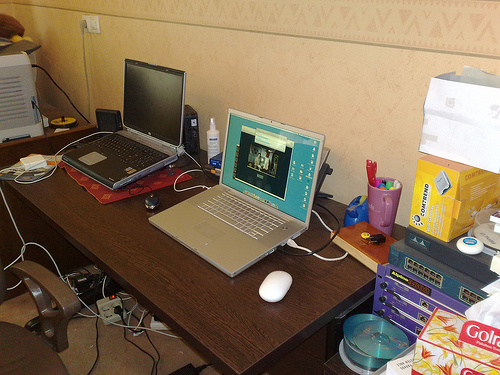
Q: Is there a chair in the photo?
A: Yes, there is a chair.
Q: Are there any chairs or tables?
A: Yes, there is a chair.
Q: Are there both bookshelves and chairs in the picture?
A: No, there is a chair but no bookshelves.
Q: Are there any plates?
A: No, there are no plates.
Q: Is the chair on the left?
A: Yes, the chair is on the left of the image.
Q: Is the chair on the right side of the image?
A: No, the chair is on the left of the image.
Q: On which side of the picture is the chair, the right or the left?
A: The chair is on the left of the image.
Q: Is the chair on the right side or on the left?
A: The chair is on the left of the image.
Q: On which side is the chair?
A: The chair is on the left of the image.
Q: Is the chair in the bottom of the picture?
A: Yes, the chair is in the bottom of the image.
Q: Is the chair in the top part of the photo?
A: No, the chair is in the bottom of the image.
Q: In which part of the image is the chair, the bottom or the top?
A: The chair is in the bottom of the image.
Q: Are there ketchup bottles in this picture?
A: No, there are no ketchup bottles.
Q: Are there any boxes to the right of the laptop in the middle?
A: Yes, there is a box to the right of the laptop.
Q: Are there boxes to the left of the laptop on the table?
A: No, the box is to the right of the laptop.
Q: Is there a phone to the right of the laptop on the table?
A: No, there is a box to the right of the laptop.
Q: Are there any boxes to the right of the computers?
A: Yes, there is a box to the right of the computers.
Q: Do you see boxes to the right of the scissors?
A: Yes, there is a box to the right of the scissors.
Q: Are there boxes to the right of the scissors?
A: Yes, there is a box to the right of the scissors.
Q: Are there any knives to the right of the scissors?
A: No, there is a box to the right of the scissors.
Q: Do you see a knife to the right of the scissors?
A: No, there is a box to the right of the scissors.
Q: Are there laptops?
A: Yes, there is a laptop.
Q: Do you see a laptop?
A: Yes, there is a laptop.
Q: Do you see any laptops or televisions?
A: Yes, there is a laptop.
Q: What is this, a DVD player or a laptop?
A: This is a laptop.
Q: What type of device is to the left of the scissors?
A: The device is a laptop.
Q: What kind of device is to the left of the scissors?
A: The device is a laptop.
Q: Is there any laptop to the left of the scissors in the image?
A: Yes, there is a laptop to the left of the scissors.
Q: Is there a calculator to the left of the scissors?
A: No, there is a laptop to the left of the scissors.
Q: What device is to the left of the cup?
A: The device is a laptop.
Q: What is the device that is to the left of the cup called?
A: The device is a laptop.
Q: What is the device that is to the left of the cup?
A: The device is a laptop.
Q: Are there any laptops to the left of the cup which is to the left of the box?
A: Yes, there is a laptop to the left of the cup.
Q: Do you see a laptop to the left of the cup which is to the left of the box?
A: Yes, there is a laptop to the left of the cup.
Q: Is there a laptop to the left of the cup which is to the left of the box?
A: Yes, there is a laptop to the left of the cup.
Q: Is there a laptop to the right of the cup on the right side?
A: No, the laptop is to the left of the cup.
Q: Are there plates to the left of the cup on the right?
A: No, there is a laptop to the left of the cup.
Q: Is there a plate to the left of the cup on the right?
A: No, there is a laptop to the left of the cup.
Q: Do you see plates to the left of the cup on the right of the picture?
A: No, there is a laptop to the left of the cup.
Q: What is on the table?
A: The laptop is on the table.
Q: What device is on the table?
A: The device is a laptop.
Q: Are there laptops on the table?
A: Yes, there is a laptop on the table.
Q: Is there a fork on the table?
A: No, there is a laptop on the table.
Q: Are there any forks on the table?
A: No, there is a laptop on the table.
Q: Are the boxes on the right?
A: Yes, the boxes are on the right of the image.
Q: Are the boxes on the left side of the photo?
A: No, the boxes are on the right of the image.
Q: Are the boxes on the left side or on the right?
A: The boxes are on the right of the image.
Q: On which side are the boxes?
A: The boxes are on the right of the image.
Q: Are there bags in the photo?
A: No, there are no bags.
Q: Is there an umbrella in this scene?
A: No, there are no umbrellas.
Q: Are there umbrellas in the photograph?
A: No, there are no umbrellas.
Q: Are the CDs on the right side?
A: Yes, the CDs are on the right of the image.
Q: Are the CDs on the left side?
A: No, the CDs are on the right of the image.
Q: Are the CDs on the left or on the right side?
A: The CDs are on the right of the image.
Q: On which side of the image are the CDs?
A: The CDs are on the right of the image.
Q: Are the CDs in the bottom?
A: Yes, the CDs are in the bottom of the image.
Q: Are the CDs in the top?
A: No, the CDs are in the bottom of the image.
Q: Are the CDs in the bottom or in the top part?
A: The CDs are in the bottom of the image.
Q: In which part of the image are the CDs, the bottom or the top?
A: The CDs are in the bottom of the image.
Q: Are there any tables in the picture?
A: Yes, there is a table.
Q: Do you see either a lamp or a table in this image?
A: Yes, there is a table.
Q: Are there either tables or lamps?
A: Yes, there is a table.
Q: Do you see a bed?
A: No, there are no beds.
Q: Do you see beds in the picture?
A: No, there are no beds.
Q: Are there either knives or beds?
A: No, there are no beds or knives.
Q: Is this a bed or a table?
A: This is a table.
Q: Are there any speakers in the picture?
A: No, there are no speakers.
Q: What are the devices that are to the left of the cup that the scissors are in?
A: The devices are computers.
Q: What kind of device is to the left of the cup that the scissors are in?
A: The devices are computers.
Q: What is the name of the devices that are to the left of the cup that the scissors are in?
A: The devices are computers.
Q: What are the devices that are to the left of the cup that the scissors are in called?
A: The devices are computers.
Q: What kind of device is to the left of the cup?
A: The devices are computers.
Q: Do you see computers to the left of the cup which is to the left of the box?
A: Yes, there are computers to the left of the cup.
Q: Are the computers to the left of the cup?
A: Yes, the computers are to the left of the cup.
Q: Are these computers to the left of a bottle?
A: No, the computers are to the left of the cup.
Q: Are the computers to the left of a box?
A: Yes, the computers are to the left of a box.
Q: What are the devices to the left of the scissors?
A: The devices are computers.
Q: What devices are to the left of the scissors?
A: The devices are computers.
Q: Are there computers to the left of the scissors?
A: Yes, there are computers to the left of the scissors.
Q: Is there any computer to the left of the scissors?
A: Yes, there are computers to the left of the scissors.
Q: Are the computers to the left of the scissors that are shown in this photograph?
A: Yes, the computers are to the left of the scissors.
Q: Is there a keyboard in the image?
A: Yes, there is a keyboard.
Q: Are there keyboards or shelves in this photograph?
A: Yes, there is a keyboard.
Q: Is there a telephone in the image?
A: No, there are no phones.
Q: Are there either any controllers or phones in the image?
A: No, there are no phones or controllers.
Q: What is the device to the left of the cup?
A: The device is a keyboard.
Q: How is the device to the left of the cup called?
A: The device is a keyboard.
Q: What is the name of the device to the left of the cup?
A: The device is a keyboard.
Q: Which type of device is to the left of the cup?
A: The device is a keyboard.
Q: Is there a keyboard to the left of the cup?
A: Yes, there is a keyboard to the left of the cup.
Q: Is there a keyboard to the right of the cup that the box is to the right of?
A: No, the keyboard is to the left of the cup.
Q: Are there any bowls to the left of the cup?
A: No, there is a keyboard to the left of the cup.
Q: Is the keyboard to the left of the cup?
A: Yes, the keyboard is to the left of the cup.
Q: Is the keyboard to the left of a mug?
A: No, the keyboard is to the left of the cup.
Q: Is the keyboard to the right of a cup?
A: No, the keyboard is to the left of a cup.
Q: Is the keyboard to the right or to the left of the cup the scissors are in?
A: The keyboard is to the left of the cup.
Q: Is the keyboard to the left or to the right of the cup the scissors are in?
A: The keyboard is to the left of the cup.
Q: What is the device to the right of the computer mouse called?
A: The device is a keyboard.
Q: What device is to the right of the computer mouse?
A: The device is a keyboard.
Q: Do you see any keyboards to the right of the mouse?
A: Yes, there is a keyboard to the right of the mouse.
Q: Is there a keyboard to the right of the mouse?
A: Yes, there is a keyboard to the right of the mouse.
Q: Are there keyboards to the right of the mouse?
A: Yes, there is a keyboard to the right of the mouse.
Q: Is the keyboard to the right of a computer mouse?
A: Yes, the keyboard is to the right of a computer mouse.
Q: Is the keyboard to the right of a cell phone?
A: No, the keyboard is to the right of a computer mouse.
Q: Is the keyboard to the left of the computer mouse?
A: No, the keyboard is to the right of the computer mouse.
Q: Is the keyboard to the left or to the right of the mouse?
A: The keyboard is to the right of the mouse.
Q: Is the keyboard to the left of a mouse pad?
A: No, the keyboard is to the left of the box.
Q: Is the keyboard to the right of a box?
A: No, the keyboard is to the left of a box.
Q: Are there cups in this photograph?
A: Yes, there is a cup.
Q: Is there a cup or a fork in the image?
A: Yes, there is a cup.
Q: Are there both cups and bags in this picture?
A: No, there is a cup but no bags.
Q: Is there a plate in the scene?
A: No, there are no plates.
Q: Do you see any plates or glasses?
A: No, there are no plates or glasses.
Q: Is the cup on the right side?
A: Yes, the cup is on the right of the image.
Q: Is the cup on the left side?
A: No, the cup is on the right of the image.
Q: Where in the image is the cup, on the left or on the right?
A: The cup is on the right of the image.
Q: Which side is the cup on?
A: The cup is on the right of the image.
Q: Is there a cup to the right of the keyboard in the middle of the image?
A: Yes, there is a cup to the right of the keyboard.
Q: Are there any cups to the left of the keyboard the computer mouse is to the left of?
A: No, the cup is to the right of the keyboard.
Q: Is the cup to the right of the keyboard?
A: Yes, the cup is to the right of the keyboard.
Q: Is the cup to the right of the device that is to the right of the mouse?
A: Yes, the cup is to the right of the keyboard.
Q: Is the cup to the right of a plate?
A: No, the cup is to the right of the keyboard.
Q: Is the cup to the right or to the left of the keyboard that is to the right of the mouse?
A: The cup is to the right of the keyboard.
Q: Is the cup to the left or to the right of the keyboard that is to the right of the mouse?
A: The cup is to the right of the keyboard.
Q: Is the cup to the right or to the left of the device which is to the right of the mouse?
A: The cup is to the right of the keyboard.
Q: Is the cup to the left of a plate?
A: No, the cup is to the left of the box.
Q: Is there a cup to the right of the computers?
A: Yes, there is a cup to the right of the computers.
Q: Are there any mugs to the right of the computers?
A: No, there is a cup to the right of the computers.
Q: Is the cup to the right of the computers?
A: Yes, the cup is to the right of the computers.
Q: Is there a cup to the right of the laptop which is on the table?
A: Yes, there is a cup to the right of the laptop.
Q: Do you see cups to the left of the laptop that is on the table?
A: No, the cup is to the right of the laptop computer.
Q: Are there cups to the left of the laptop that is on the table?
A: No, the cup is to the right of the laptop computer.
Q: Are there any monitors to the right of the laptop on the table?
A: No, there is a cup to the right of the laptop.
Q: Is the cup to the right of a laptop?
A: Yes, the cup is to the right of a laptop.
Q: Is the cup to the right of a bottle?
A: No, the cup is to the right of a laptop.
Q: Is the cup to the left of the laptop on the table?
A: No, the cup is to the right of the laptop.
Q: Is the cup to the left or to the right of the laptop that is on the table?
A: The cup is to the right of the laptop.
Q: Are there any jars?
A: No, there are no jars.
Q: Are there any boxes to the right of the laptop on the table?
A: Yes, there is a box to the right of the laptop.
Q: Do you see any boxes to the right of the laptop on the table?
A: Yes, there is a box to the right of the laptop.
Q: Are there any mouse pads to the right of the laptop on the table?
A: No, there is a box to the right of the laptop.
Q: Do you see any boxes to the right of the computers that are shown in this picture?
A: Yes, there is a box to the right of the computers.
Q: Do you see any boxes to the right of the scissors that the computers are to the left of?
A: Yes, there is a box to the right of the scissors.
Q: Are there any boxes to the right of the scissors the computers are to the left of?
A: Yes, there is a box to the right of the scissors.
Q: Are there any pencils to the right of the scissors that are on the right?
A: No, there is a box to the right of the scissors.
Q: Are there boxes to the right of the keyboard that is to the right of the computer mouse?
A: Yes, there is a box to the right of the keyboard.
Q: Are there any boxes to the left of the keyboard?
A: No, the box is to the right of the keyboard.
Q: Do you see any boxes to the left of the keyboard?
A: No, the box is to the right of the keyboard.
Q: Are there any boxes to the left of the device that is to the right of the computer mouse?
A: No, the box is to the right of the keyboard.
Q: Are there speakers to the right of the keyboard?
A: No, there is a box to the right of the keyboard.